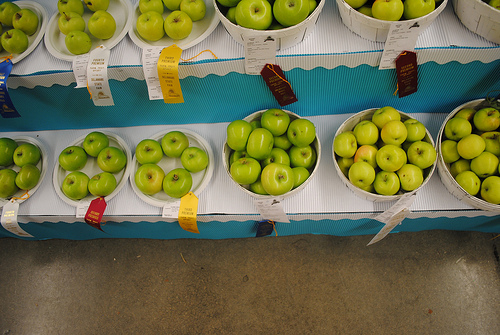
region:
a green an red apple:
[351, 142, 384, 167]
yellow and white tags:
[143, 46, 191, 113]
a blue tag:
[0, 62, 15, 117]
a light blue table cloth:
[106, 220, 166, 238]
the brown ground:
[245, 270, 385, 334]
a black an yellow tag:
[246, 217, 283, 238]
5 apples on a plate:
[141, 131, 212, 193]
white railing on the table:
[125, 212, 164, 227]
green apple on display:
[57, 144, 86, 172]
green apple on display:
[84, 133, 110, 159]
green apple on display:
[96, 144, 128, 173]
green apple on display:
[58, 166, 90, 200]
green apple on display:
[88, 166, 116, 196]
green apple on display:
[135, 138, 162, 164]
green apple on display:
[159, 129, 189, 156]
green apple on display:
[177, 147, 207, 172]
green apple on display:
[134, 159, 164, 199]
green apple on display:
[161, 166, 193, 195]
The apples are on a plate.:
[1, 130, 51, 215]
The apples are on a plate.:
[46, 118, 131, 215]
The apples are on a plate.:
[126, 122, 217, 215]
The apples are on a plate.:
[43, 0, 137, 65]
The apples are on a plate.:
[126, 0, 219, 62]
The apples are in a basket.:
[217, 103, 325, 207]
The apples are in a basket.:
[330, 100, 440, 205]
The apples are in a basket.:
[432, 91, 499, 222]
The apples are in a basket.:
[211, 0, 333, 57]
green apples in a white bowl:
[212, 0, 324, 52]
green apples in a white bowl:
[435, 97, 497, 210]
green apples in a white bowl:
[331, 106, 438, 203]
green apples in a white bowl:
[220, 108, 321, 201]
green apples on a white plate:
[0, 137, 45, 202]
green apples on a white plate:
[50, 130, 130, 205]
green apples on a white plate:
[130, 128, 212, 205]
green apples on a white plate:
[126, 0, 217, 50]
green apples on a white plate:
[42, 0, 129, 60]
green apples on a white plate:
[0, 1, 47, 65]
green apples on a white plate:
[0, 136, 47, 206]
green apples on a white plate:
[128, 128, 213, 209]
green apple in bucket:
[383, 120, 406, 147]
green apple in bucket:
[372, 143, 405, 168]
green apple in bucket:
[407, 136, 435, 168]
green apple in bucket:
[396, 158, 426, 188]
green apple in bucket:
[372, 165, 397, 193]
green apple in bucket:
[346, 158, 376, 185]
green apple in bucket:
[260, 105, 295, 140]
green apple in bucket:
[286, 115, 315, 145]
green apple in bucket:
[227, 158, 260, 187]